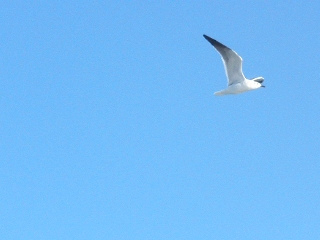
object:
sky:
[0, 0, 320, 240]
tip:
[203, 33, 233, 51]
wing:
[202, 33, 246, 84]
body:
[213, 80, 259, 95]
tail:
[214, 90, 225, 96]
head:
[253, 82, 266, 90]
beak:
[261, 85, 266, 88]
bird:
[202, 34, 267, 97]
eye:
[257, 83, 259, 85]